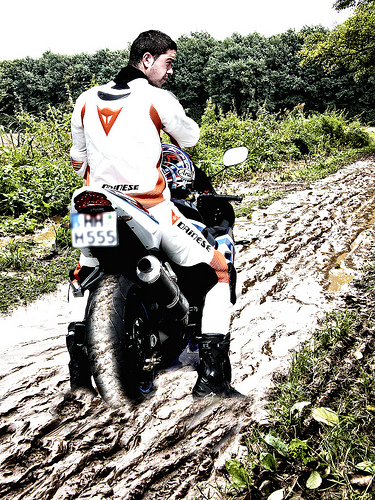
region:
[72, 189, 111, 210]
Stop light on a motorcycle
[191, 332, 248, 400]
Black leather motorcycle boot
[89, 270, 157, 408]
Rear wheel of a motorcycle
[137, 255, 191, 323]
Exhaust pipe on a motorcycle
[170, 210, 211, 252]
Manufacturer logo on motorcycle clothing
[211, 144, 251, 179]
Rearview mirror on a motorcycle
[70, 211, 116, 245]
License plate on a motorcycle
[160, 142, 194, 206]
Front side of motorcycle helmet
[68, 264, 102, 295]
Rear foot peg on a motorcycle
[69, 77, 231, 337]
White leathers worn by motorcycle rider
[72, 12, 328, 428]
a man riding a motorbike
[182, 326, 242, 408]
the boots are black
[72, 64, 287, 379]
the race suit is white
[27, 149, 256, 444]
the bike in the mud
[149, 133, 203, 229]
the helmet on the bike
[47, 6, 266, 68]
the sky is clear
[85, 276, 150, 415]
the tire has mud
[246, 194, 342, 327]
tire tracks on mud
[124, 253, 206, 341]
smoke pipe is silver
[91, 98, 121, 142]
the logo is orange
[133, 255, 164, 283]
The exhaust opening of a motorbike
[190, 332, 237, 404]
The black shoe of the rider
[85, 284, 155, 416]
The rear wheel of the motorbike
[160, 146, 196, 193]
The cyclist's safety helmet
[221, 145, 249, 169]
The side mirror of a motorbike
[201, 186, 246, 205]
The handle bar of a motorbike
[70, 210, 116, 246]
The registration plate of a motorbike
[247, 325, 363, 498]
Wet and muddy vegetation on road side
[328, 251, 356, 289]
A pool of muddy water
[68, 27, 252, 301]
A rider on his motorbike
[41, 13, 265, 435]
A man riding a bike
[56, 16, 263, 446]
A man on a bike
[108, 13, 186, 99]
This is a head of a man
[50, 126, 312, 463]
This is a bike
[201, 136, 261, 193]
This is a side mirror of a bike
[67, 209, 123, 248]
This is a registration number of the bike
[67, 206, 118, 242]
This is a registration plate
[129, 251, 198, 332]
This is an exhaust pipe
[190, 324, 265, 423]
These are safety boots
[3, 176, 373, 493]
This is a mud road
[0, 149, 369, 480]
The ground is muddy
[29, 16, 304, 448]
Man riding dirt bike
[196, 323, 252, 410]
Man is wearing black boots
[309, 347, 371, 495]
There is green grass in the foreground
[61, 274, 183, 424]
The tires are muddy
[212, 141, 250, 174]
The bike has side mirrors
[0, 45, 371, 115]
The trees in the distance are green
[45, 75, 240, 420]
The mans gear is orange and white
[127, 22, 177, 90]
The man has short hair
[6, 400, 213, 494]
There are tracks in the mud